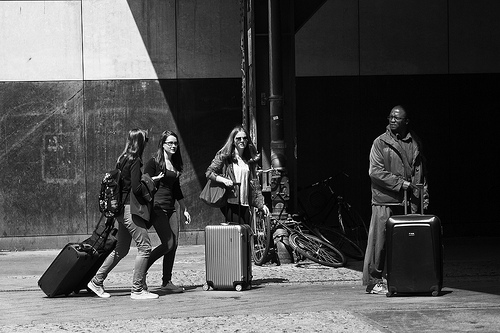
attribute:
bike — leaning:
[309, 167, 372, 261]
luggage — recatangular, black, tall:
[384, 214, 441, 297]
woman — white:
[87, 128, 166, 301]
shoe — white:
[132, 290, 160, 300]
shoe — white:
[88, 280, 111, 301]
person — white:
[144, 129, 193, 293]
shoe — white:
[158, 283, 185, 293]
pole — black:
[267, 2, 298, 265]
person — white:
[205, 125, 271, 287]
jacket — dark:
[369, 125, 429, 214]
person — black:
[362, 106, 429, 296]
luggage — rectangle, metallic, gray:
[205, 222, 253, 290]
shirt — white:
[232, 154, 249, 209]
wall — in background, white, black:
[1, 2, 499, 237]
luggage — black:
[38, 239, 101, 296]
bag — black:
[97, 157, 142, 218]